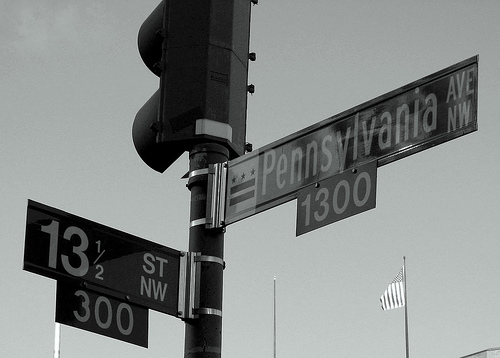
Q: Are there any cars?
A: No, there are no cars.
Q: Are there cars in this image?
A: No, there are no cars.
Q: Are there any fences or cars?
A: No, there are no cars or fences.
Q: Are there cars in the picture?
A: No, there are no cars.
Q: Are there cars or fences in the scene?
A: No, there are no cars or fences.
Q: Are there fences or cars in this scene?
A: No, there are no cars or fences.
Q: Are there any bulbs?
A: No, there are no bulbs.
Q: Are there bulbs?
A: No, there are no bulbs.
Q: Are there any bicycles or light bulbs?
A: No, there are no light bulbs or bicycles.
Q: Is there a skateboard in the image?
A: No, there are no skateboards.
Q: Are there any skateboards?
A: No, there are no skateboards.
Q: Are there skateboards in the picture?
A: No, there are no skateboards.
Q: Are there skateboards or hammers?
A: No, there are no skateboards or hammers.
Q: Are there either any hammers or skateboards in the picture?
A: No, there are no skateboards or hammers.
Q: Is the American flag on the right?
A: Yes, the American flag is on the right of the image.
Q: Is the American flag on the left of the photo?
A: No, the American flag is on the right of the image.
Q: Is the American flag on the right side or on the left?
A: The American flag is on the right of the image.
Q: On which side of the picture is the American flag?
A: The American flag is on the right of the image.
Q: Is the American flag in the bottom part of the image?
A: Yes, the American flag is in the bottom of the image.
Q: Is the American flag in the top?
A: No, the American flag is in the bottom of the image.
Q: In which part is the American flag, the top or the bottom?
A: The American flag is in the bottom of the image.